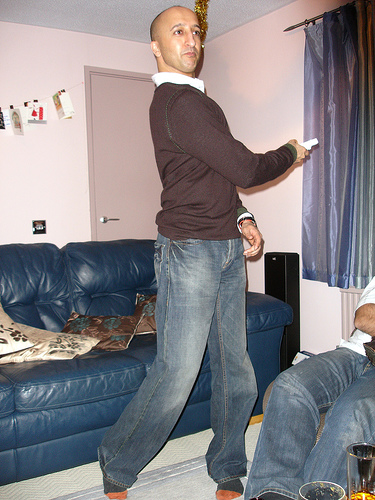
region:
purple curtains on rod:
[295, 4, 373, 286]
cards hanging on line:
[0, 80, 83, 135]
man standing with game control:
[98, 5, 318, 496]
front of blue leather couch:
[0, 239, 291, 485]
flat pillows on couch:
[0, 295, 156, 360]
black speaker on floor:
[263, 252, 298, 369]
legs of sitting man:
[251, 347, 371, 498]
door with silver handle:
[87, 72, 175, 238]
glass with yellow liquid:
[348, 443, 374, 498]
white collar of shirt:
[153, 71, 204, 91]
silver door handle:
[98, 215, 122, 223]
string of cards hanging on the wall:
[0, 89, 74, 137]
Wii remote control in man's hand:
[300, 134, 318, 151]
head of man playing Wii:
[149, 6, 202, 72]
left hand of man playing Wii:
[238, 216, 264, 262]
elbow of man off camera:
[353, 306, 373, 336]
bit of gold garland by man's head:
[195, 0, 211, 39]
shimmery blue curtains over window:
[296, 5, 371, 283]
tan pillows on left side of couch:
[1, 301, 99, 365]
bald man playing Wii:
[95, 3, 317, 498]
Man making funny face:
[95, 7, 270, 498]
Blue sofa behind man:
[3, 232, 305, 484]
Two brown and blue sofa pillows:
[33, 271, 184, 369]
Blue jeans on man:
[100, 222, 258, 490]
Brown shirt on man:
[139, 58, 321, 254]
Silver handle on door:
[97, 215, 124, 226]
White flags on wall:
[7, 72, 106, 168]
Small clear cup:
[343, 436, 374, 499]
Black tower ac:
[260, 241, 315, 396]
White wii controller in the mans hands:
[296, 134, 326, 160]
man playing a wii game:
[130, 6, 315, 466]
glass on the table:
[345, 441, 371, 499]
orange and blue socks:
[208, 479, 246, 498]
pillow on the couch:
[52, 304, 141, 354]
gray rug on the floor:
[166, 458, 202, 494]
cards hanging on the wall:
[0, 83, 85, 145]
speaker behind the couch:
[263, 246, 302, 303]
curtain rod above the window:
[279, 16, 309, 31]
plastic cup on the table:
[293, 478, 348, 498]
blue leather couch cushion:
[10, 370, 105, 406]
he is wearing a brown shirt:
[128, 58, 318, 243]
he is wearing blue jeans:
[81, 232, 265, 498]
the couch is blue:
[0, 227, 308, 490]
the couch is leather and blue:
[0, 216, 319, 488]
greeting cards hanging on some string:
[3, 76, 91, 152]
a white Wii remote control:
[280, 121, 329, 172]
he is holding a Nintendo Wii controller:
[137, 6, 342, 277]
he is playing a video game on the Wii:
[76, 1, 343, 499]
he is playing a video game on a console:
[31, 1, 354, 499]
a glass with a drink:
[340, 438, 373, 498]